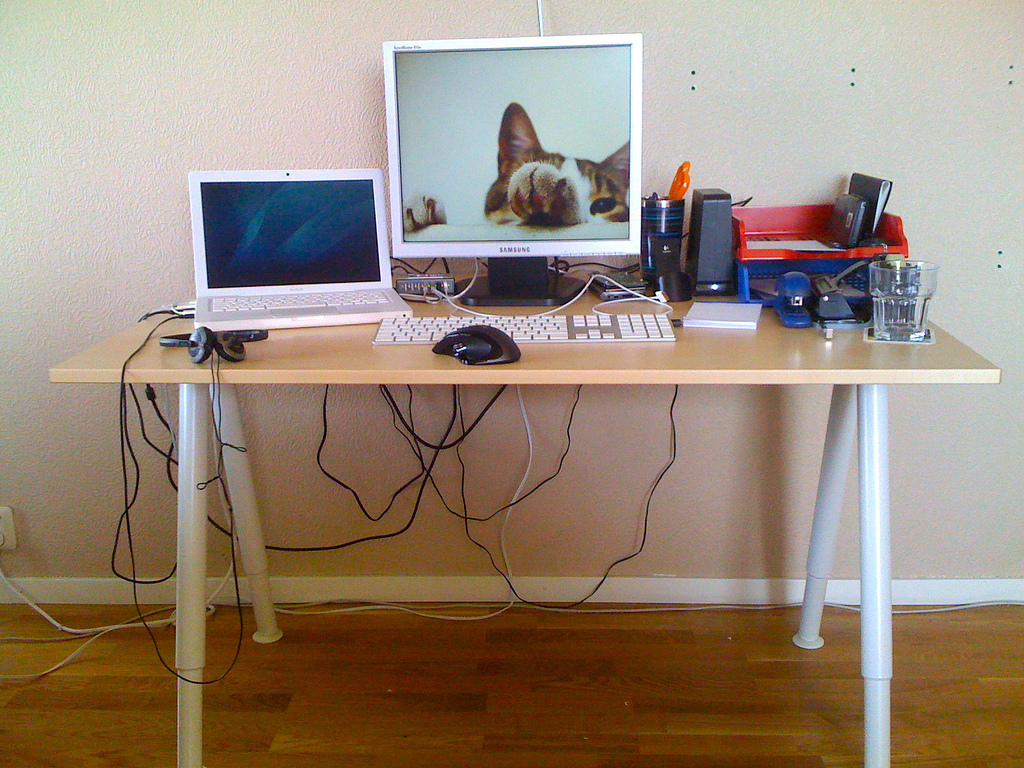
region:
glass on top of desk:
[870, 253, 929, 340]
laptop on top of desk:
[181, 171, 404, 331]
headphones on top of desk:
[164, 323, 270, 361]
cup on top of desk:
[639, 188, 682, 284]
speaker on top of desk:
[685, 183, 739, 297]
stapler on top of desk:
[761, 273, 815, 325]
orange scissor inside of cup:
[661, 164, 704, 196]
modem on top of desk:
[401, 269, 455, 301]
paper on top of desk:
[683, 289, 763, 332]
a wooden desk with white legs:
[49, 303, 999, 766]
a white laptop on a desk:
[184, 166, 409, 331]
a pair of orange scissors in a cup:
[669, 159, 692, 202]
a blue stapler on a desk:
[772, 267, 817, 325]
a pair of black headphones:
[157, 327, 265, 366]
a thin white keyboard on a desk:
[373, 314, 677, 343]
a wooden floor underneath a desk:
[0, 600, 1023, 766]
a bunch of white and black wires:
[11, 254, 1020, 688]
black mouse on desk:
[422, 326, 525, 364]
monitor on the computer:
[385, 28, 642, 269]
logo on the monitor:
[498, 236, 541, 256]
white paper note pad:
[679, 300, 763, 339]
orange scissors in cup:
[665, 157, 701, 206]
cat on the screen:
[479, 95, 635, 233]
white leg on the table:
[842, 388, 937, 761]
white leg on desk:
[211, 382, 304, 651]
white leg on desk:
[793, 382, 858, 649]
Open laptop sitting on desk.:
[185, 160, 410, 331]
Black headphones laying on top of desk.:
[150, 323, 267, 362]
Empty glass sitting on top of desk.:
[863, 256, 936, 343]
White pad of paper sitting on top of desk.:
[677, 296, 764, 332]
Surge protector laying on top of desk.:
[392, 270, 462, 299]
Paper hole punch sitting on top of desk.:
[807, 256, 871, 329]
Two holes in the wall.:
[686, 62, 699, 94]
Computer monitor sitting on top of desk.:
[375, 29, 645, 308]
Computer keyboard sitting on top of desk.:
[368, 308, 678, 353]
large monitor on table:
[351, 37, 669, 303]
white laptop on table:
[190, 127, 362, 320]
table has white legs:
[827, 385, 973, 765]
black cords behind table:
[49, 373, 692, 607]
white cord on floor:
[20, 426, 561, 654]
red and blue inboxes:
[725, 195, 868, 326]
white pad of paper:
[681, 279, 780, 352]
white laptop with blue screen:
[167, 157, 417, 369]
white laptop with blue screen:
[164, 160, 418, 353]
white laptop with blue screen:
[161, 151, 462, 361]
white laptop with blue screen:
[166, 160, 487, 398]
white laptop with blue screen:
[167, 145, 444, 376]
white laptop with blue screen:
[179, 158, 446, 380]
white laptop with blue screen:
[167, 148, 462, 390]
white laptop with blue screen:
[182, 158, 440, 378]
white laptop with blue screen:
[177, 158, 452, 392]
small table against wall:
[48, 273, 997, 758]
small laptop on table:
[179, 147, 408, 353]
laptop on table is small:
[177, 162, 412, 347]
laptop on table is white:
[187, 160, 422, 341]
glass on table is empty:
[857, 255, 944, 348]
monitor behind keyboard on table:
[371, 23, 656, 271]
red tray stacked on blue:
[722, 195, 918, 272]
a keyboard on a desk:
[373, 306, 671, 348]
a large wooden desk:
[59, 298, 944, 726]